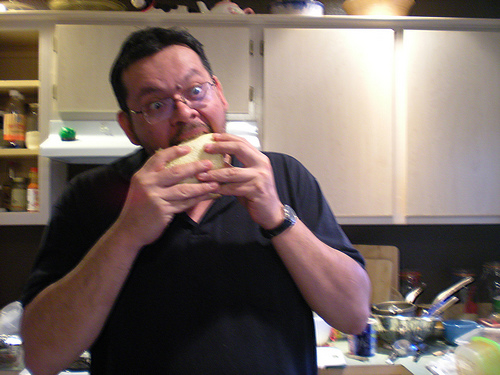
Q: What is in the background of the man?
A: Cabinets.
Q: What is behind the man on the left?
A: An opened cabinet with seasonings.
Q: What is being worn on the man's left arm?
A: A watch.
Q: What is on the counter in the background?
A: Pots and pans.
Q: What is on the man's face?
A: Glasses.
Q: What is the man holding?
A: A sandwich.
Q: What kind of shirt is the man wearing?
A: A black short sleeved shirt.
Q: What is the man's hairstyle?
A: Short and straight.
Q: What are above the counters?
A: Cabinets.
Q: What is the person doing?
A: Eating.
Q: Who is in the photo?
A: A man.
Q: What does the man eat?
A: A sandwich.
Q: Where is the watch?
A: On the wrist.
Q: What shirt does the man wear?
A: A black shirt.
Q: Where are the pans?
A: Behind the man.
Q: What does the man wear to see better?
A: Glasses.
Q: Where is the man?
A: In a kitchen.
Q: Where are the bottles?
A: In the cabinet.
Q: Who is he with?
A: No one.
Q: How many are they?
A: 1.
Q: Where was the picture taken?
A: In a kitchen.